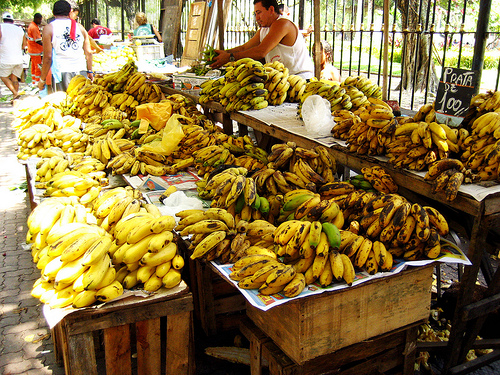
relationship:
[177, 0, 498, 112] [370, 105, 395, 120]
fence behind banana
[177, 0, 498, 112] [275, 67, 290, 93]
fence behind banana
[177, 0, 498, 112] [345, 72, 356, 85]
fence behind banana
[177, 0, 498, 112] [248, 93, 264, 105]
fence behind banana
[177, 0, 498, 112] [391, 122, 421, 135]
fence behind banana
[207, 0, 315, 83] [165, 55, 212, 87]
man taking from box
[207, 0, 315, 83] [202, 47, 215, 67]
man taking fruit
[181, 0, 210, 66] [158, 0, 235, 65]
tables leaning against wall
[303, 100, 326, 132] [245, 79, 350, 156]
plastic on table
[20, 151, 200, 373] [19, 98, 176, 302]
table of bananas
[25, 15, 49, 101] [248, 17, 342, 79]
man in shirt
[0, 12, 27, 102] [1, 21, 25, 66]
man in shirt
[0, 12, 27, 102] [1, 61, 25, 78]
man in pants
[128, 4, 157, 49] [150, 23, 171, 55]
woman has purse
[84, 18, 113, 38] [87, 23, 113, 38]
man has shirt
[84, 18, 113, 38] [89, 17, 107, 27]
man has hat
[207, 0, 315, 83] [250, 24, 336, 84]
man in shirt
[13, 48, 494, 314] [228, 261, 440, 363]
bananas on crate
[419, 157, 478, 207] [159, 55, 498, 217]
bananas hanging off table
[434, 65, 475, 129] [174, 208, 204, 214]
sign behind banana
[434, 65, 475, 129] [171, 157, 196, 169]
sign behind banana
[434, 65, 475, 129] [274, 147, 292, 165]
sign behind banana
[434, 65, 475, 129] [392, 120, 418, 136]
sign behind banana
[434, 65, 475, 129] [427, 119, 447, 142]
sign behind banana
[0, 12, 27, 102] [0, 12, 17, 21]
man in white cap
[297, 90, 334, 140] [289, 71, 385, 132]
bag in front of bananas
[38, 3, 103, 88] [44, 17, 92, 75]
man has tank top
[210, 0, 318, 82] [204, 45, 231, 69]
man has hands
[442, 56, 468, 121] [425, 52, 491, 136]
numbers on sign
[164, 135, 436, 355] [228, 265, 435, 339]
newspaper on box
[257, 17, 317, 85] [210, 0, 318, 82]
shirt on man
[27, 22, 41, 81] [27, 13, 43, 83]
clothes on man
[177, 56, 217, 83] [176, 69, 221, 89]
fruit in box made of cardboard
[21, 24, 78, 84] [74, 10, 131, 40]
shirt on man